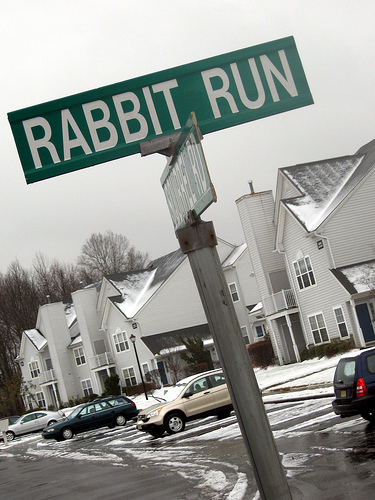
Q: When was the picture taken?
A: Daytime.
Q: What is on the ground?
A: Snow.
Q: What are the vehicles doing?
A: Parked.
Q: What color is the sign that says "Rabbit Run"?
A: Green.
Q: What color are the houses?
A: Gray.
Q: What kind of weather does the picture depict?
A: Cold.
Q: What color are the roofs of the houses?
A: Black.